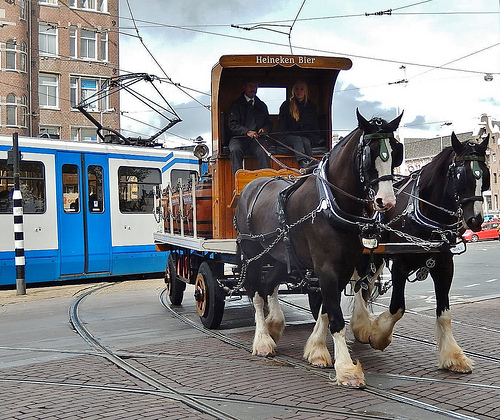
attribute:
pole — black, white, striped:
[12, 133, 27, 293]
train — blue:
[0, 135, 210, 288]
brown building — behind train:
[2, 3, 121, 141]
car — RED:
[464, 230, 483, 238]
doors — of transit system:
[59, 153, 127, 280]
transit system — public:
[3, 115, 157, 293]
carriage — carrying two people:
[151, 40, 496, 392]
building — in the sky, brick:
[0, 2, 129, 131]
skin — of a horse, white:
[320, 237, 343, 256]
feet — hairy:
[248, 310, 377, 399]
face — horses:
[350, 117, 405, 217]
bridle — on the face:
[358, 172, 397, 226]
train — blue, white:
[0, 107, 210, 281]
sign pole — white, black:
[2, 125, 34, 297]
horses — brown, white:
[224, 108, 483, 407]